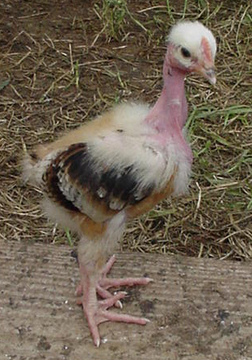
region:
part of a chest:
[182, 131, 184, 211]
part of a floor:
[176, 294, 205, 326]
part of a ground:
[157, 316, 191, 340]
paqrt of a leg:
[79, 306, 97, 331]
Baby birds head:
[157, 17, 222, 93]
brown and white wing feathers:
[51, 142, 173, 219]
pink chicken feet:
[75, 252, 157, 352]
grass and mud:
[2, 1, 130, 98]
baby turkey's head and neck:
[142, 14, 228, 143]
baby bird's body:
[27, 14, 164, 237]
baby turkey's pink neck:
[138, 61, 202, 160]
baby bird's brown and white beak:
[199, 65, 221, 87]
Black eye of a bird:
[172, 39, 199, 71]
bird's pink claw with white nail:
[88, 327, 109, 348]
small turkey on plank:
[33, 23, 224, 326]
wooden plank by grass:
[12, 249, 249, 354]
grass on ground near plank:
[18, 33, 250, 210]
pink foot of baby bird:
[64, 286, 127, 345]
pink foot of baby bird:
[82, 258, 146, 294]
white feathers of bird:
[104, 135, 137, 167]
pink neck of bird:
[141, 66, 185, 131]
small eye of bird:
[177, 44, 192, 59]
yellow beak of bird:
[195, 65, 227, 85]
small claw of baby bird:
[91, 335, 105, 348]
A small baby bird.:
[15, 20, 228, 350]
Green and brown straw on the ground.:
[0, 1, 248, 262]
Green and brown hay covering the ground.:
[1, 0, 250, 264]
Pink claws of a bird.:
[71, 252, 154, 347]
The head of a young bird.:
[162, 18, 220, 90]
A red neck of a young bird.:
[147, 20, 220, 140]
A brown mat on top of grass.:
[2, 237, 249, 359]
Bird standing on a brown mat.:
[15, 20, 220, 357]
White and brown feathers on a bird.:
[18, 19, 219, 236]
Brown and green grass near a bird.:
[2, 1, 251, 251]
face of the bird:
[138, 17, 243, 93]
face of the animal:
[174, 30, 233, 103]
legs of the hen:
[70, 275, 158, 331]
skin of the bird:
[84, 137, 154, 182]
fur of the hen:
[96, 149, 129, 179]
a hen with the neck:
[131, 60, 199, 115]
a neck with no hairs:
[155, 68, 203, 158]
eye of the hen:
[176, 33, 201, 70]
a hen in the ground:
[10, 24, 244, 351]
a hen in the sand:
[10, 10, 235, 359]